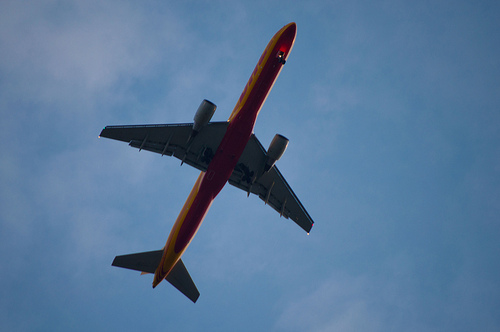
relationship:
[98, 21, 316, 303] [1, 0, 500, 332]
airplane in blue sky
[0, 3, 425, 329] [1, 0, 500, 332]
clouds in blue sky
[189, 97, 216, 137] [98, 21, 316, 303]
engine on airplane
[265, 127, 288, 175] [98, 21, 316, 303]
engine on airplane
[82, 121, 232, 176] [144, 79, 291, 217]
wing on plane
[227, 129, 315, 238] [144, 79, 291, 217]
wing on plane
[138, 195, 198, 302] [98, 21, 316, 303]
orange tail on airplane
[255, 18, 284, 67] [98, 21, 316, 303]
light on airplane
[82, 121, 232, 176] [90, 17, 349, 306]
wing of plane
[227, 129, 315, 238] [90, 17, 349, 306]
wing of plane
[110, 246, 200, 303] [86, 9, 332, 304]
tail of plane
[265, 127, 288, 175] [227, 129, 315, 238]
engine under wing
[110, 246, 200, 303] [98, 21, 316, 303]
tail of airplane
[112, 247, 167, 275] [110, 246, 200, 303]
wings on tail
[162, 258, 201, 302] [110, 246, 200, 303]
wings on tail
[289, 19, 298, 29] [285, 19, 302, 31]
point of nose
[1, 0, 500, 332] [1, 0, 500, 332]
blue sky in blue sky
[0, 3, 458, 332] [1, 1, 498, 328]
clouds in blue sky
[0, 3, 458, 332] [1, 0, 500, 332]
clouds in blue sky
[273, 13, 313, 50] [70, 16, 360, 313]
nose of plane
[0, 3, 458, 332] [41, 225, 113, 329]
clouds in sky